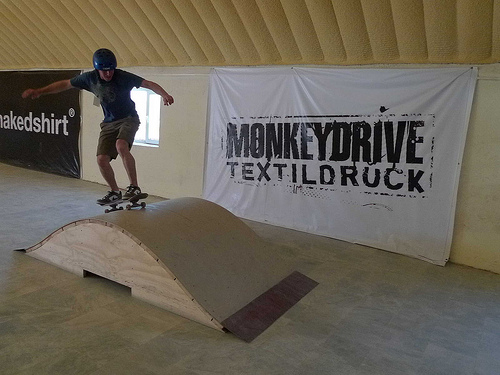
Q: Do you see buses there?
A: No, there are no buses.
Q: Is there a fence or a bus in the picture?
A: No, there are no buses or fences.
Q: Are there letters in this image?
A: Yes, there are letters.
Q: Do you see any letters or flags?
A: Yes, there are letters.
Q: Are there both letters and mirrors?
A: No, there are letters but no mirrors.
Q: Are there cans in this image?
A: No, there are no cans.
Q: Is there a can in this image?
A: No, there are no cans.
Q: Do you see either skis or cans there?
A: No, there are no cans or skis.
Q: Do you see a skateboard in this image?
A: Yes, there is a skateboard.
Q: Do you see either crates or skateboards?
A: Yes, there is a skateboard.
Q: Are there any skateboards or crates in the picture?
A: Yes, there is a skateboard.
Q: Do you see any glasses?
A: No, there are no glasses.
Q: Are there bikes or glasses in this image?
A: No, there are no glasses or bikes.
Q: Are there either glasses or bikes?
A: No, there are no glasses or bikes.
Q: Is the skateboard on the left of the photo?
A: Yes, the skateboard is on the left of the image.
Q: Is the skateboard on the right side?
A: No, the skateboard is on the left of the image.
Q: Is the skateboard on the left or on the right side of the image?
A: The skateboard is on the left of the image.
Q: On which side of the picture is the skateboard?
A: The skateboard is on the left of the image.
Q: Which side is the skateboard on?
A: The skateboard is on the left of the image.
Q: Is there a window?
A: Yes, there is a window.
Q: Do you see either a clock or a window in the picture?
A: Yes, there is a window.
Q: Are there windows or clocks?
A: Yes, there is a window.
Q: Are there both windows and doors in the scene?
A: No, there is a window but no doors.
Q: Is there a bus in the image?
A: No, there are no buses.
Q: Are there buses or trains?
A: No, there are no buses or trains.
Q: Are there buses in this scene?
A: No, there are no buses.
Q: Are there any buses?
A: No, there are no buses.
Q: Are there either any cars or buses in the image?
A: No, there are no buses or cars.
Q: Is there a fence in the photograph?
A: No, there are no fences.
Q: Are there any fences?
A: No, there are no fences.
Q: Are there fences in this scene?
A: No, there are no fences.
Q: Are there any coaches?
A: No, there are no coaches.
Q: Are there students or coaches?
A: No, there are no coaches or students.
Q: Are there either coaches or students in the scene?
A: No, there are no coaches or students.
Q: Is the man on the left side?
A: Yes, the man is on the left of the image.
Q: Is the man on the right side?
A: No, the man is on the left of the image.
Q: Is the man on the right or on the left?
A: The man is on the left of the image.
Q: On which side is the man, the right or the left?
A: The man is on the left of the image.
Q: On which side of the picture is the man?
A: The man is on the left of the image.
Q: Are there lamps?
A: No, there are no lamps.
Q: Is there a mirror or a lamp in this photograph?
A: No, there are no lamps or mirrors.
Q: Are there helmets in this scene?
A: Yes, there is a helmet.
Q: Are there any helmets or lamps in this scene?
A: Yes, there is a helmet.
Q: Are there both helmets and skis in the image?
A: No, there is a helmet but no skis.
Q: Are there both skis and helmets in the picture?
A: No, there is a helmet but no skis.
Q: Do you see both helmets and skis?
A: No, there is a helmet but no skis.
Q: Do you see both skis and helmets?
A: No, there is a helmet but no skis.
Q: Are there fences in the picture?
A: No, there are no fences.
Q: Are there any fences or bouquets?
A: No, there are no fences or bouquets.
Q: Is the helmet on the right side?
A: No, the helmet is on the left of the image.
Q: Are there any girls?
A: No, there are no girls.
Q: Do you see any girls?
A: No, there are no girls.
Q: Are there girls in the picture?
A: No, there are no girls.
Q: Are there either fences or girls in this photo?
A: No, there are no girls or fences.